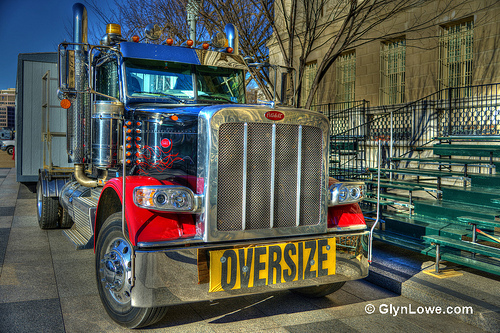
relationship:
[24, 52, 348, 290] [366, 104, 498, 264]
truck by bleachers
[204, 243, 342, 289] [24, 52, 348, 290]
sign on truck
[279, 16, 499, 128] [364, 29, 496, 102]
building has windows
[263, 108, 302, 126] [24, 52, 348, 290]
logo on truck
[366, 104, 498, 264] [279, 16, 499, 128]
bleachers by building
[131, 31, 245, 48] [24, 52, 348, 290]
lights on truck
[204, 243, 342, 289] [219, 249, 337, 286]
sign has writing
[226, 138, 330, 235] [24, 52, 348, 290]
grill on truck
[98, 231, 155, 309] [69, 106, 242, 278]
tire on diesel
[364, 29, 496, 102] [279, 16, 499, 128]
windows on building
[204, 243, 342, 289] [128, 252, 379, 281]
sign on bumper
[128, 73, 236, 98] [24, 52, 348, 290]
windshield on truck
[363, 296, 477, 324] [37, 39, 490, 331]
name on picture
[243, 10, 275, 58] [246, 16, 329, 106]
branches on tree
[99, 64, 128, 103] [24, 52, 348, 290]
window on truck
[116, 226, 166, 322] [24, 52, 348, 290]
wheel on truck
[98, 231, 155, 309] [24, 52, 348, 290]
tire on truck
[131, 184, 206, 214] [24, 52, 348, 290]
headlight on truck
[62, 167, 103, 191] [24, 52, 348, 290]
muffler on truck